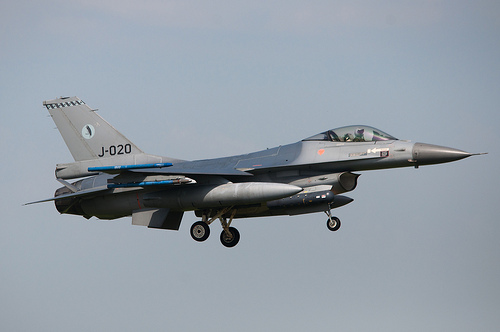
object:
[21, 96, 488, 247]
air plane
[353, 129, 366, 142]
pilot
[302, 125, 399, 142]
cockpit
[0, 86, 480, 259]
plane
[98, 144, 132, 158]
lettering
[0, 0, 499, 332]
smoky sky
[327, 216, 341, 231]
black/white tire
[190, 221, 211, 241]
black/white tire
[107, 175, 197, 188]
bombs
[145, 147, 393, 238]
warfare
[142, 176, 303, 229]
weapons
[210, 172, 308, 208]
war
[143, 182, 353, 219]
fuel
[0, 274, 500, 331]
base